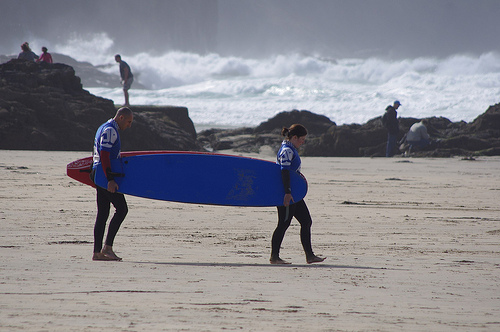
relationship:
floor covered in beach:
[218, 234, 327, 293] [0, 150, 497, 332]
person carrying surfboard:
[271, 120, 328, 270] [65, 146, 310, 210]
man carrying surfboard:
[90, 106, 133, 261] [65, 146, 310, 210]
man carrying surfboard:
[90, 106, 133, 261] [69, 103, 441, 305]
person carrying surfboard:
[271, 120, 328, 270] [69, 103, 441, 305]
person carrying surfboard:
[270, 123, 328, 264] [66, 151, 308, 207]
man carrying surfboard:
[90, 106, 133, 261] [66, 151, 308, 207]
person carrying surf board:
[270, 123, 328, 264] [91, 145, 311, 209]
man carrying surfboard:
[82, 100, 139, 272] [65, 129, 305, 250]